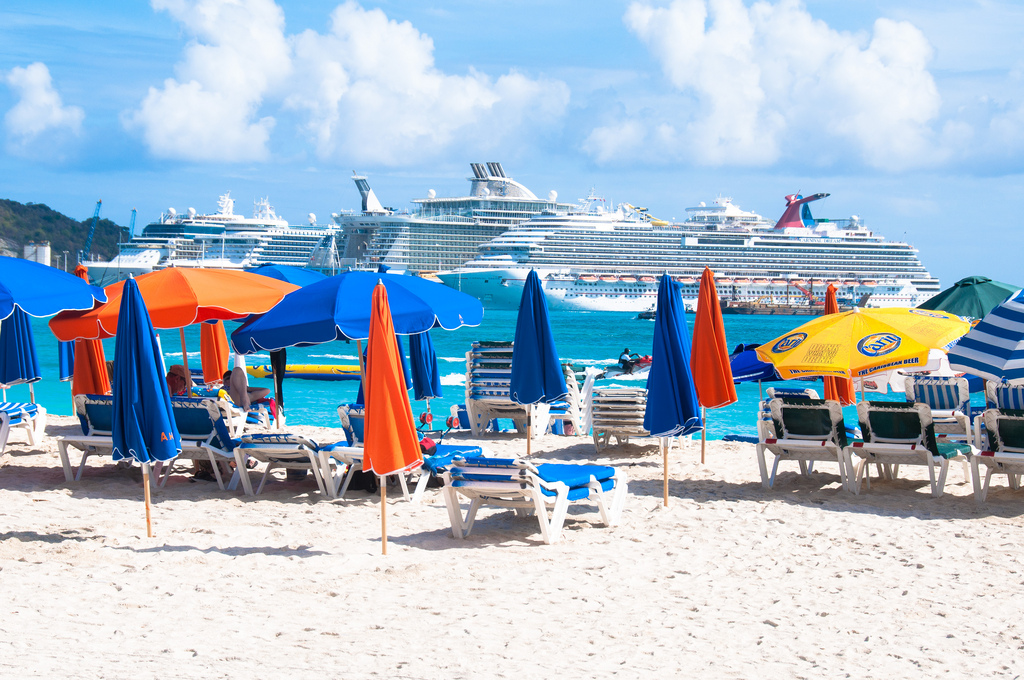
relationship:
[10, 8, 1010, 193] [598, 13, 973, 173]
blue sky full of clouds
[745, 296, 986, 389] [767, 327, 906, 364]
open umbrella with symbols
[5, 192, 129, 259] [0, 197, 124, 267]
green hill in background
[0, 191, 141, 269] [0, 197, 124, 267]
green hill in background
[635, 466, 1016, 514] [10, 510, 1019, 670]
shadow on sand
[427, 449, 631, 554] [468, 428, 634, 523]
chair with blue cushions